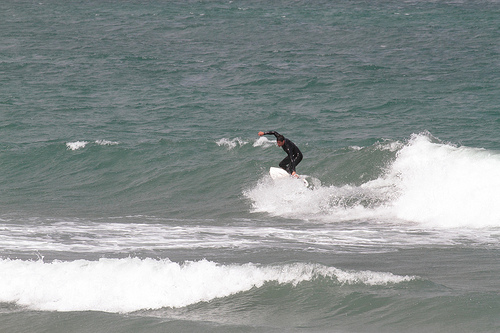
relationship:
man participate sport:
[255, 124, 311, 178] [199, 112, 324, 201]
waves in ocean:
[0, 122, 500, 326] [2, 0, 499, 332]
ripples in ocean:
[0, 3, 500, 330] [2, 0, 499, 332]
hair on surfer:
[275, 131, 286, 143] [253, 126, 304, 176]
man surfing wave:
[257, 130, 304, 178] [44, 115, 499, 233]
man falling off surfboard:
[257, 130, 304, 178] [262, 161, 292, 184]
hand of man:
[256, 129, 275, 137] [257, 130, 304, 178]